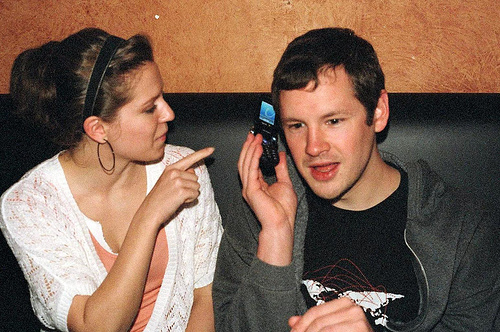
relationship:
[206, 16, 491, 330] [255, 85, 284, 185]
man on cell phone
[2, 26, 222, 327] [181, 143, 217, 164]
woman has finger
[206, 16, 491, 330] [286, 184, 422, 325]
man wears shirt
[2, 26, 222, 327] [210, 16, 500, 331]
woman pointing at man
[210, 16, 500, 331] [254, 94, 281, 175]
man on phone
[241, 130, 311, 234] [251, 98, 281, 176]
hand with cellphone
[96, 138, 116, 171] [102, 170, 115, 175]
earring casting shadow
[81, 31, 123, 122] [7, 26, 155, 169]
band holding hair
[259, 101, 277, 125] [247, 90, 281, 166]
screen built into cell phone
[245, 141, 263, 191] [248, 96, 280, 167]
finger holding cell phone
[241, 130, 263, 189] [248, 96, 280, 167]
finger holding cell phone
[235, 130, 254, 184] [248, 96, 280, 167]
finger holding cell phone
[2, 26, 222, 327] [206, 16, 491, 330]
woman pointing at man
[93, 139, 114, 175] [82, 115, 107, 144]
earring hanging from ear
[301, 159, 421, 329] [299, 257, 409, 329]
shirt with design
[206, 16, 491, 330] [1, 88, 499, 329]
man sitting on couch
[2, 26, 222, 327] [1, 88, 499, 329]
woman sitting on couch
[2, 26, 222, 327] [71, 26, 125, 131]
woman wears a headband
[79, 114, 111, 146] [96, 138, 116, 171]
ear has earring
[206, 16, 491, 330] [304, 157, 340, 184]
man has mouth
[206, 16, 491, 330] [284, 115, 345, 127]
man has eyes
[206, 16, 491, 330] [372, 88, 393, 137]
man has ear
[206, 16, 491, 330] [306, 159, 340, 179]
man has mouth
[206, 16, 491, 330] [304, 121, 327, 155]
man has nose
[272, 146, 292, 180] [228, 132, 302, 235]
thumb on cellphone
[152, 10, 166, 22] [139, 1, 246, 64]
spot on wall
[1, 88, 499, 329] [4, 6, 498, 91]
couch against wall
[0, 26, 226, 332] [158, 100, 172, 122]
woman has a nose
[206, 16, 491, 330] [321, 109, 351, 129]
man has eye